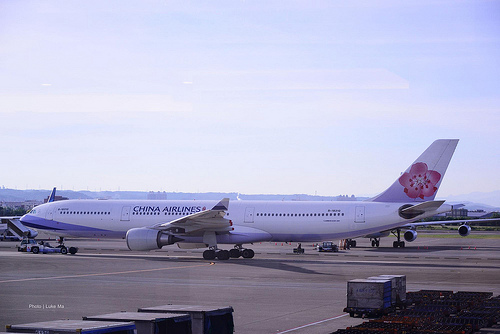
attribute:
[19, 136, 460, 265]
airplane — large, white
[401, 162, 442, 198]
flower — pink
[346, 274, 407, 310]
cargo boxes — gray, blue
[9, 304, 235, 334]
cargo boxes — gray, blue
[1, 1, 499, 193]
sky — blue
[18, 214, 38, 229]
nose — blue, white